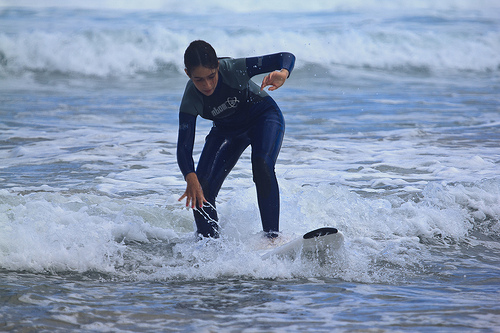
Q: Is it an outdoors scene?
A: Yes, it is outdoors.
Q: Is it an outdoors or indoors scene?
A: It is outdoors.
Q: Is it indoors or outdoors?
A: It is outdoors.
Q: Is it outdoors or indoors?
A: It is outdoors.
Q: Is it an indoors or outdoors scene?
A: It is outdoors.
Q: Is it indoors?
A: No, it is outdoors.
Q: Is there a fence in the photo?
A: No, there are no fences.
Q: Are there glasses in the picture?
A: No, there are no glasses.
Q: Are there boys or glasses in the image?
A: No, there are no glasses or boys.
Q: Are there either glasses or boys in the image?
A: No, there are no glasses or boys.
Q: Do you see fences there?
A: No, there are no fences.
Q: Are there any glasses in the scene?
A: No, there are no glasses.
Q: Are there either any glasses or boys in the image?
A: No, there are no glasses or boys.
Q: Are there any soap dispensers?
A: No, there are no soap dispensers.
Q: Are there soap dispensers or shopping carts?
A: No, there are no soap dispensers or shopping carts.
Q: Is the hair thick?
A: Yes, the hair is thick.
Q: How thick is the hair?
A: The hair is thick.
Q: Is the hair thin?
A: No, the hair is thick.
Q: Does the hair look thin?
A: No, the hair is thick.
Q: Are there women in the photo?
A: Yes, there is a woman.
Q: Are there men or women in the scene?
A: Yes, there is a woman.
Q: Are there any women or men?
A: Yes, there is a woman.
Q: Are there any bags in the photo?
A: No, there are no bags.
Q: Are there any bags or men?
A: No, there are no bags or men.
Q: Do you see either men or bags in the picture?
A: No, there are no bags or men.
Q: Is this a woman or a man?
A: This is a woman.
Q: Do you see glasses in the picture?
A: No, there are no glasses.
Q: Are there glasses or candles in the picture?
A: No, there are no glasses or candles.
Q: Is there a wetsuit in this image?
A: Yes, there is a wetsuit.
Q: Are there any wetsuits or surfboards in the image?
A: Yes, there is a wetsuit.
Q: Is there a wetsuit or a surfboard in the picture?
A: Yes, there is a wetsuit.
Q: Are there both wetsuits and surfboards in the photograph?
A: Yes, there are both a wetsuit and a surfboard.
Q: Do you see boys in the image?
A: No, there are no boys.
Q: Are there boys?
A: No, there are no boys.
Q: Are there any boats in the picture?
A: No, there are no boats.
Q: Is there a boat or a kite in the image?
A: No, there are no boats or kites.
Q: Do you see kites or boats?
A: No, there are no boats or kites.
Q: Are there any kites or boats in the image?
A: No, there are no boats or kites.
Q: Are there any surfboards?
A: Yes, there is a surfboard.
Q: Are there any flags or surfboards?
A: Yes, there is a surfboard.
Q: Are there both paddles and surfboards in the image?
A: No, there is a surfboard but no paddles.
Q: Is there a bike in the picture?
A: No, there are no bikes.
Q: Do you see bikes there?
A: No, there are no bikes.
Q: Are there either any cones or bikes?
A: No, there are no bikes or cones.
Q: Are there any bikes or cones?
A: No, there are no bikes or cones.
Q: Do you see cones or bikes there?
A: No, there are no bikes or cones.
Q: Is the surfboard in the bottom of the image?
A: Yes, the surfboard is in the bottom of the image.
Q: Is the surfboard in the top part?
A: No, the surfboard is in the bottom of the image.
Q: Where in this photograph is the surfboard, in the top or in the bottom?
A: The surfboard is in the bottom of the image.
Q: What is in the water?
A: The surfboard is in the water.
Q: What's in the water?
A: The surfboard is in the water.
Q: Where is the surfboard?
A: The surfboard is in the water.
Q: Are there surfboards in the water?
A: Yes, there is a surfboard in the water.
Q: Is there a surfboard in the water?
A: Yes, there is a surfboard in the water.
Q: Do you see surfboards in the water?
A: Yes, there is a surfboard in the water.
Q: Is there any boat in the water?
A: No, there is a surfboard in the water.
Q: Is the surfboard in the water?
A: Yes, the surfboard is in the water.